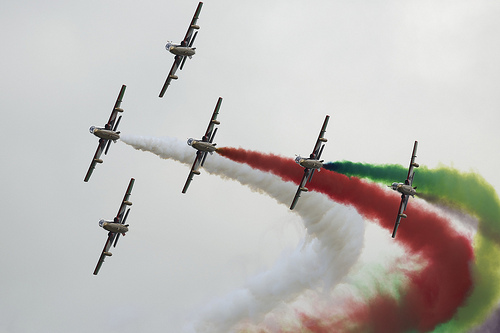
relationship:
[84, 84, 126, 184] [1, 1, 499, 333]
plane flying in sky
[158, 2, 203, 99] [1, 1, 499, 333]
plane flying in sky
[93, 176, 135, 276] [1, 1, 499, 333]
plane flying in sky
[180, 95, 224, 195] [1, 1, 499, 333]
plane flying in sky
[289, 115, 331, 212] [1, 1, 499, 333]
plane flying in sky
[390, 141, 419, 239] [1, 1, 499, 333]
plane flying in sky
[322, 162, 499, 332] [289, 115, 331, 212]
smoke coming out of plane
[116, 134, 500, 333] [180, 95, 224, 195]
smoke coming out of plane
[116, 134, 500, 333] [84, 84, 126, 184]
smoke coming out of plane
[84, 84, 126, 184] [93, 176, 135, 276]
plane flying close to plane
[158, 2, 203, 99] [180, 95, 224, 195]
plane flying close to plane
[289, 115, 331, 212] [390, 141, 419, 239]
plane flying close to plane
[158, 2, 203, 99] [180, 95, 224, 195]
plane flying near plane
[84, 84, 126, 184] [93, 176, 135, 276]
plane flying near plane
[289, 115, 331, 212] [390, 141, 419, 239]
plane flying near plane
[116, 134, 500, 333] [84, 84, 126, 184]
smoke being released from plane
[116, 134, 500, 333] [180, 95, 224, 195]
smoke being released from plane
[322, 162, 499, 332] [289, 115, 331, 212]
smoke being released from plane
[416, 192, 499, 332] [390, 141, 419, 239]
smoke being released from plane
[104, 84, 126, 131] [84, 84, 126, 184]
wing of plane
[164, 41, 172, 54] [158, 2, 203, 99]
propeller of plane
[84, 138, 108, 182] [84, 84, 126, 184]
wing of plane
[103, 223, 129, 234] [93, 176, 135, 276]
body of plane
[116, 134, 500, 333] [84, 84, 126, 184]
smoke from plane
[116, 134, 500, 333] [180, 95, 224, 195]
smoke from plane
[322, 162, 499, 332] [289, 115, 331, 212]
smoke from plane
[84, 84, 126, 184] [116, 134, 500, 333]
plane putting out smoke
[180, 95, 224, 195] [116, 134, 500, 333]
plane putting out smoke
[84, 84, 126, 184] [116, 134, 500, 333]
plane releasing smoke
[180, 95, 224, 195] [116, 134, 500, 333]
plane releasing smoke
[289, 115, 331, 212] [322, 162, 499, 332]
plane releasing smoke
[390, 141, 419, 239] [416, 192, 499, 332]
plane releasing smoke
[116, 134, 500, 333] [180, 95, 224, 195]
smoke behind plane